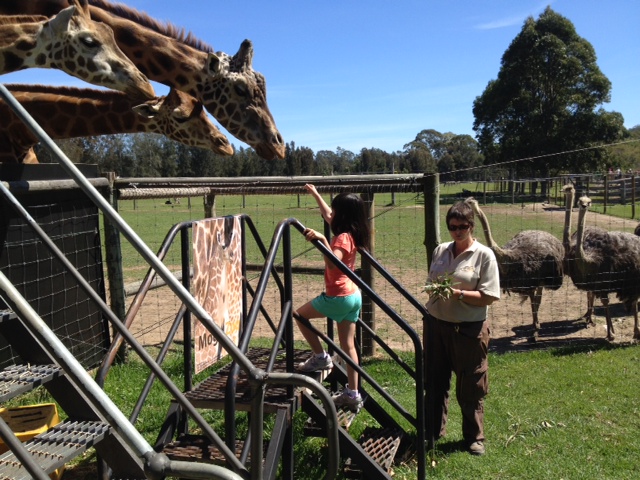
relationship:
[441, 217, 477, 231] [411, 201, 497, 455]
sunglasses on woman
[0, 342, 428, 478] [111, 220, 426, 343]
metal stairs with rails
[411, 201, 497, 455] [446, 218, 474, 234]
woman with sunglasses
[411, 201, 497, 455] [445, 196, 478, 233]
woman with hair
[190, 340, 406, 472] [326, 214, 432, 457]
stairs with rails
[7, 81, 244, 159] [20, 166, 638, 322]
giraffe in pen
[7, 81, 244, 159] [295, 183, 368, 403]
giraffe reaching toward girl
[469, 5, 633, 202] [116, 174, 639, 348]
tree by fence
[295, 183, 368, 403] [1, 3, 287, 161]
girl feeding giraffe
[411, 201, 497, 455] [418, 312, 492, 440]
woman wearing pants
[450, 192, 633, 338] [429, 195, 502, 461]
ostrich behind woman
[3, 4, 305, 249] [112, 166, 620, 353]
giraffes leaning over fence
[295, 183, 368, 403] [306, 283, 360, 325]
girl watching shorts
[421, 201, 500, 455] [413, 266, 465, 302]
woman holding food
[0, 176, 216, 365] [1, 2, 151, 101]
fencing in front of giraffe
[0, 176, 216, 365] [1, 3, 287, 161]
fencing in front of giraffe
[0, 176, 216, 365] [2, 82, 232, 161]
fencing in front of giraffe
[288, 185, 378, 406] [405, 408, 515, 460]
girl wearing shoes